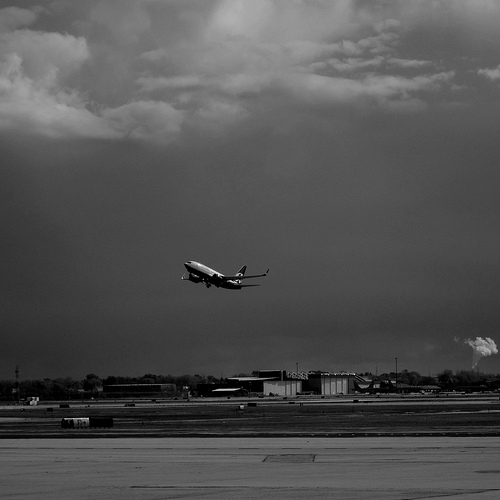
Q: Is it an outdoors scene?
A: Yes, it is outdoors.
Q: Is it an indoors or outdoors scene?
A: It is outdoors.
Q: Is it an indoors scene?
A: No, it is outdoors.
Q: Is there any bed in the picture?
A: No, there are no beds.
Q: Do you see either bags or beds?
A: No, there are no beds or bags.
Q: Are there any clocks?
A: No, there are no clocks.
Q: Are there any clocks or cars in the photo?
A: No, there are no clocks or cars.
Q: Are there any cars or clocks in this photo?
A: No, there are no clocks or cars.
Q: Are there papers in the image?
A: No, there are no papers.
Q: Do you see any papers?
A: No, there are no papers.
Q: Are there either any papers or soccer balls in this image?
A: No, there are no papers or soccer balls.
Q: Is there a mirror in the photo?
A: No, there are no mirrors.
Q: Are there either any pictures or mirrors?
A: No, there are no mirrors or pictures.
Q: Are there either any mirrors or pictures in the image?
A: No, there are no mirrors or pictures.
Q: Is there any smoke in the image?
A: Yes, there is smoke.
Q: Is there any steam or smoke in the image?
A: Yes, there is smoke.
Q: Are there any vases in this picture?
A: No, there are no vases.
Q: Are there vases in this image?
A: No, there are no vases.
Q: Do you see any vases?
A: No, there are no vases.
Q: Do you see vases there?
A: No, there are no vases.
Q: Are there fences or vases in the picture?
A: No, there are no vases or fences.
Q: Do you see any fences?
A: No, there are no fences.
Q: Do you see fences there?
A: No, there are no fences.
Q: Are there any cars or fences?
A: No, there are no fences or cars.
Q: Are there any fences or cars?
A: No, there are no fences or cars.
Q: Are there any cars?
A: No, there are no cars.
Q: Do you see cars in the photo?
A: No, there are no cars.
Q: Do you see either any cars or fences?
A: No, there are no cars or fences.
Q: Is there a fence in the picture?
A: No, there are no fences.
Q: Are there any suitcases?
A: No, there are no suitcases.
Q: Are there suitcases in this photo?
A: No, there are no suitcases.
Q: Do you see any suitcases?
A: No, there are no suitcases.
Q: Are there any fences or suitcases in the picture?
A: No, there are no suitcases or fences.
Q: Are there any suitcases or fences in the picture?
A: No, there are no suitcases or fences.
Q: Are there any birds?
A: No, there are no birds.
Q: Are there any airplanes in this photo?
A: Yes, there is an airplane.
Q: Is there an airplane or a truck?
A: Yes, there is an airplane.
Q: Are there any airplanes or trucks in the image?
A: Yes, there is an airplane.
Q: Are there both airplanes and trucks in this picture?
A: No, there is an airplane but no trucks.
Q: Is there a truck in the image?
A: No, there are no trucks.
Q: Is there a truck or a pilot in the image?
A: No, there are no trucks or pilots.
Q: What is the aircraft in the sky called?
A: The aircraft is an airplane.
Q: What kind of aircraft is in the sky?
A: The aircraft is an airplane.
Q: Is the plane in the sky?
A: Yes, the plane is in the sky.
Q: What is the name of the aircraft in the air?
A: The aircraft is an airplane.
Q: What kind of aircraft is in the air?
A: The aircraft is an airplane.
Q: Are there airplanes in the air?
A: Yes, there is an airplane in the air.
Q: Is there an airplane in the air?
A: Yes, there is an airplane in the air.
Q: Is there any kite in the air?
A: No, there is an airplane in the air.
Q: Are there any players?
A: No, there are no players.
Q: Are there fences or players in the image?
A: No, there are no players or fences.